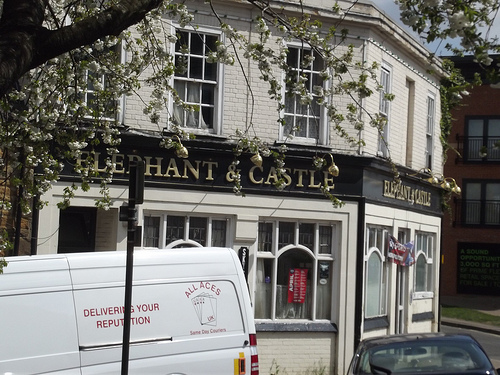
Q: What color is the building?
A: White.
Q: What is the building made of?
A: Brick.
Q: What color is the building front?
A: White.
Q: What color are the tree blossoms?
A: White.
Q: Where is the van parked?
A: In front of the building.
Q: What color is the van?
A: White.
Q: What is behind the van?
A: A car.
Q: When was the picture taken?
A: During daytime hours.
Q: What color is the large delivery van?
A: White.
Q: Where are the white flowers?
A: On tree branches.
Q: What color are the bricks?
A: White.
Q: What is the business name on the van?
A: All Aces.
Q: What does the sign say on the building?
A: Elephant & Castle.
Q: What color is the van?
A: White.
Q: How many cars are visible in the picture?
A: One.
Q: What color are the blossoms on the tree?
A: White.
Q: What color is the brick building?
A: Red.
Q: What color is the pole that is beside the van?
A: Black.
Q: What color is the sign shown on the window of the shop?
A: Red.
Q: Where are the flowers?
A: On the tree.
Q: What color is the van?
A: White.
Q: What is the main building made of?
A: Brick.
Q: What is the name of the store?
A: Elephant & Castle.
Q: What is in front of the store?
A: Van.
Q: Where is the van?
A: On the street.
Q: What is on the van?
A: Writing.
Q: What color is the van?
A: White.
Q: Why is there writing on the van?
A: Advertise.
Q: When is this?
A: Day time.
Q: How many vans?
A: 1.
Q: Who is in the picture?
A: No one.